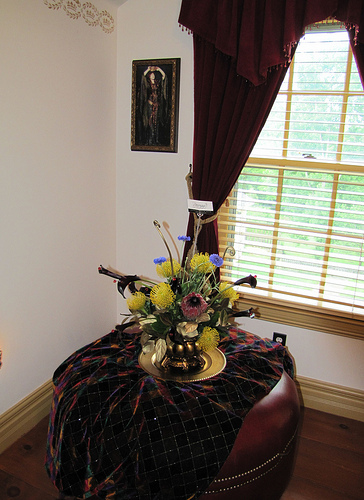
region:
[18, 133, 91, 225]
the wall is white and visible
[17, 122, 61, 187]
the wall is white and visible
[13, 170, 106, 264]
the wall is white and visible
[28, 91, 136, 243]
the wall is white and visible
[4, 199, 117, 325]
the wall is white and visible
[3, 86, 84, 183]
the wall is white and visible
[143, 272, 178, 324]
Yellow flower in vase.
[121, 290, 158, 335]
Yellow flower in vase.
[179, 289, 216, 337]
Pink flower in vase.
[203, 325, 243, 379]
Yellow flower in vase.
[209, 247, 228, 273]
Blue flower on vase.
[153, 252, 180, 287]
Blue flower on vase.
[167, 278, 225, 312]
Greenery on flowers in vase.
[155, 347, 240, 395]
Vase on gold plate.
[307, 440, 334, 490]
Dark brown hard wood floors.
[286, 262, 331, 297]
Blinds on window are positioned open.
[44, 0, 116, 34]
gold design on wall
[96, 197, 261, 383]
bouquet of yellow red and blue flowers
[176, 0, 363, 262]
burgundy window curtains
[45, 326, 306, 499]
blanket over a cushion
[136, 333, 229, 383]
gold vase on golden plate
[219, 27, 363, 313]
open wooden blinds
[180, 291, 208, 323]
an open red flower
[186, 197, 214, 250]
white place card on plastic stand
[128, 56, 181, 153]
picture of a woman in brown frame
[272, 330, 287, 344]
half a black and white outlet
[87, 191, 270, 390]
flowers in a vase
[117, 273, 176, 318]
yellow flowers in a vase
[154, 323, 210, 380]
vase with flowers is color gold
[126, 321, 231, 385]
vase is on a yellow dish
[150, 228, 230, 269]
three purple flowers on a vase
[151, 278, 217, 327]
red flower next to yellow flowers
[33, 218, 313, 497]
vase on a red stool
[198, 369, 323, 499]
a red stool under a vase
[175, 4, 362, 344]
a window with red curtains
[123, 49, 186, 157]
a picture on a white wall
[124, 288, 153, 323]
a flower in the vase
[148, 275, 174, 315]
a flower in the vase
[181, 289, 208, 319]
a flower in the vase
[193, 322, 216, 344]
a flower in the vase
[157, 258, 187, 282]
a flower in the vase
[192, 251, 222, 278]
a flower in the vase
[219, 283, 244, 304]
a flower in the vase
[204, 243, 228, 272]
a flower in the vase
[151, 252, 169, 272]
a flower in the vase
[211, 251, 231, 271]
a flower in the vase